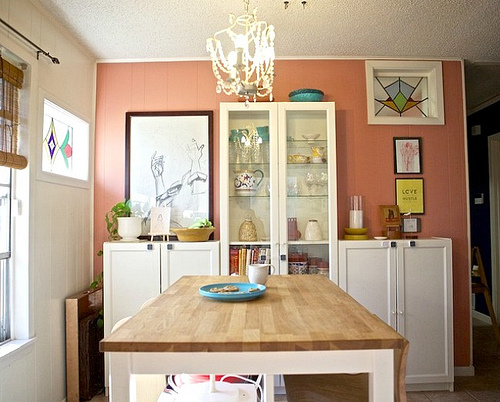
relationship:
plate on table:
[197, 273, 271, 303] [89, 260, 414, 400]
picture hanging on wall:
[130, 117, 211, 237] [91, 59, 475, 376]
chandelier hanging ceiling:
[207, 7, 282, 98] [41, 2, 498, 57]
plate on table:
[197, 282, 269, 304] [89, 260, 414, 400]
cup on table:
[245, 261, 273, 285] [89, 260, 414, 400]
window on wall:
[43, 98, 93, 183] [1, 2, 93, 399]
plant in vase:
[105, 200, 151, 242] [112, 210, 149, 244]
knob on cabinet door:
[399, 307, 411, 316] [398, 235, 453, 387]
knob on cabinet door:
[389, 307, 398, 316] [337, 239, 392, 364]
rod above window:
[0, 17, 58, 63] [1, 42, 29, 358]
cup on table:
[245, 261, 277, 285] [89, 260, 414, 400]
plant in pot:
[104, 199, 134, 243] [111, 191, 169, 239]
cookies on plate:
[207, 283, 264, 294] [199, 279, 267, 303]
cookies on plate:
[222, 284, 240, 291] [242, 277, 247, 289]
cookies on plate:
[222, 284, 240, 291] [196, 276, 266, 301]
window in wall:
[40, 99, 89, 181] [1, 2, 93, 399]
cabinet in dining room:
[102, 241, 221, 400] [0, 0, 500, 400]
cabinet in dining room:
[160, 242, 219, 283] [0, 0, 500, 400]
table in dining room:
[97, 273, 411, 400] [0, 0, 500, 400]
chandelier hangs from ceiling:
[207, 7, 282, 98] [147, 5, 341, 51]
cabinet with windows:
[219, 99, 338, 287] [227, 109, 330, 277]